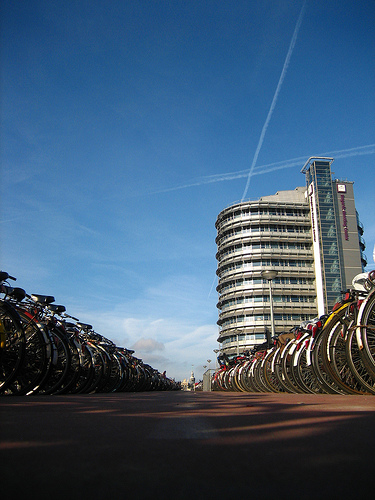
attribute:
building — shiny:
[204, 147, 372, 361]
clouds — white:
[17, 201, 109, 262]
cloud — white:
[129, 337, 167, 351]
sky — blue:
[75, 68, 210, 168]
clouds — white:
[94, 308, 220, 377]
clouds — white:
[126, 312, 216, 366]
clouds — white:
[20, 177, 200, 286]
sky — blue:
[10, 5, 367, 307]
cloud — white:
[125, 312, 246, 363]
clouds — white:
[24, 153, 75, 201]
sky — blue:
[10, 31, 69, 99]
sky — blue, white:
[160, 63, 223, 138]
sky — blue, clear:
[0, 0, 372, 388]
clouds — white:
[0, 0, 374, 379]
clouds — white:
[235, 154, 276, 186]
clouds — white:
[124, 294, 213, 356]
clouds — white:
[131, 285, 214, 358]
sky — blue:
[37, 45, 217, 147]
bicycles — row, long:
[211, 310, 360, 386]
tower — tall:
[210, 156, 343, 314]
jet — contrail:
[159, 55, 304, 195]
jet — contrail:
[217, 119, 283, 199]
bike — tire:
[233, 323, 362, 383]